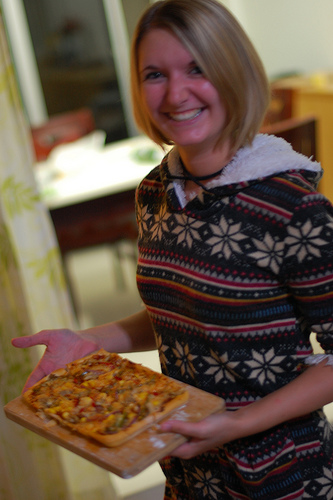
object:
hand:
[9, 327, 100, 398]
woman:
[11, 0, 332, 499]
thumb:
[11, 329, 47, 351]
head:
[129, 0, 270, 148]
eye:
[142, 69, 165, 83]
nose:
[163, 71, 190, 107]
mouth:
[157, 106, 209, 129]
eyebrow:
[138, 64, 162, 73]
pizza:
[21, 346, 189, 448]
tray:
[3, 346, 227, 479]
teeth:
[177, 111, 183, 120]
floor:
[65, 244, 145, 331]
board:
[2, 346, 227, 480]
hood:
[157, 131, 323, 206]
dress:
[134, 135, 332, 499]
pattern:
[204, 214, 249, 260]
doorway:
[0, 0, 144, 148]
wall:
[223, 0, 332, 81]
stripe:
[235, 192, 291, 220]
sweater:
[133, 134, 332, 499]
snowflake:
[246, 228, 285, 275]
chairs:
[30, 105, 120, 303]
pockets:
[225, 433, 303, 499]